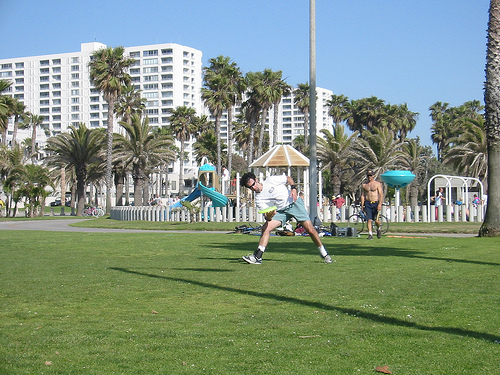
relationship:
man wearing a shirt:
[240, 172, 333, 265] [241, 178, 296, 210]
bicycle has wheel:
[348, 197, 392, 233] [341, 215, 368, 236]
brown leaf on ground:
[374, 366, 392, 374] [167, 326, 223, 359]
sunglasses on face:
[242, 177, 257, 189] [242, 178, 262, 194]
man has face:
[227, 166, 344, 271] [242, 178, 262, 194]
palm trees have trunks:
[48, 120, 104, 215] [70, 183, 92, 214]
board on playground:
[168, 182, 228, 210] [110, 155, 487, 222]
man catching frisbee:
[240, 172, 333, 265] [257, 204, 281, 218]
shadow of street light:
[108, 266, 500, 344] [291, 42, 336, 221]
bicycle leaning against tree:
[80, 203, 105, 218] [6, 162, 46, 211]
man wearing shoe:
[240, 172, 333, 265] [242, 253, 263, 265]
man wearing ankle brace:
[240, 172, 333, 265] [253, 248, 262, 259]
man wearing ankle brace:
[240, 172, 333, 265] [249, 243, 266, 261]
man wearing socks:
[240, 172, 333, 265] [254, 243, 271, 253]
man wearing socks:
[240, 172, 333, 265] [243, 244, 327, 259]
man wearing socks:
[240, 172, 333, 265] [257, 244, 329, 255]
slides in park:
[183, 164, 230, 204] [6, 90, 466, 371]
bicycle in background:
[81, 203, 104, 218] [5, 8, 496, 239]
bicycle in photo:
[81, 203, 104, 218] [1, 0, 494, 374]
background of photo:
[5, 8, 496, 239] [1, 0, 494, 374]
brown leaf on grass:
[368, 360, 395, 374] [0, 235, 499, 375]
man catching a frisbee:
[240, 172, 333, 265] [259, 203, 279, 218]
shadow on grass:
[108, 266, 500, 344] [73, 185, 464, 357]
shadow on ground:
[102, 250, 482, 360] [337, 291, 435, 334]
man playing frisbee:
[240, 172, 333, 265] [252, 203, 282, 215]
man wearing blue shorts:
[356, 167, 388, 241] [360, 197, 380, 223]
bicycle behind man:
[348, 200, 390, 234] [360, 168, 386, 238]